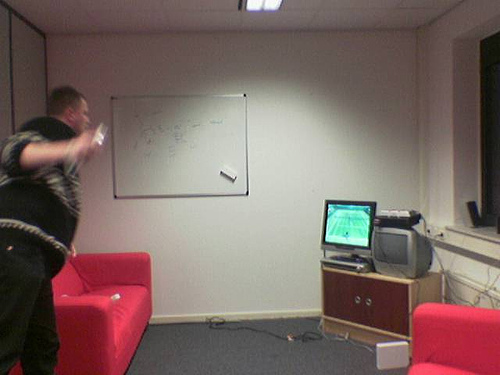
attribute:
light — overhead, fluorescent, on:
[247, 2, 280, 10]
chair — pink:
[409, 300, 499, 373]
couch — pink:
[56, 247, 159, 373]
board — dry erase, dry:
[113, 91, 248, 195]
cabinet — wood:
[312, 259, 414, 354]